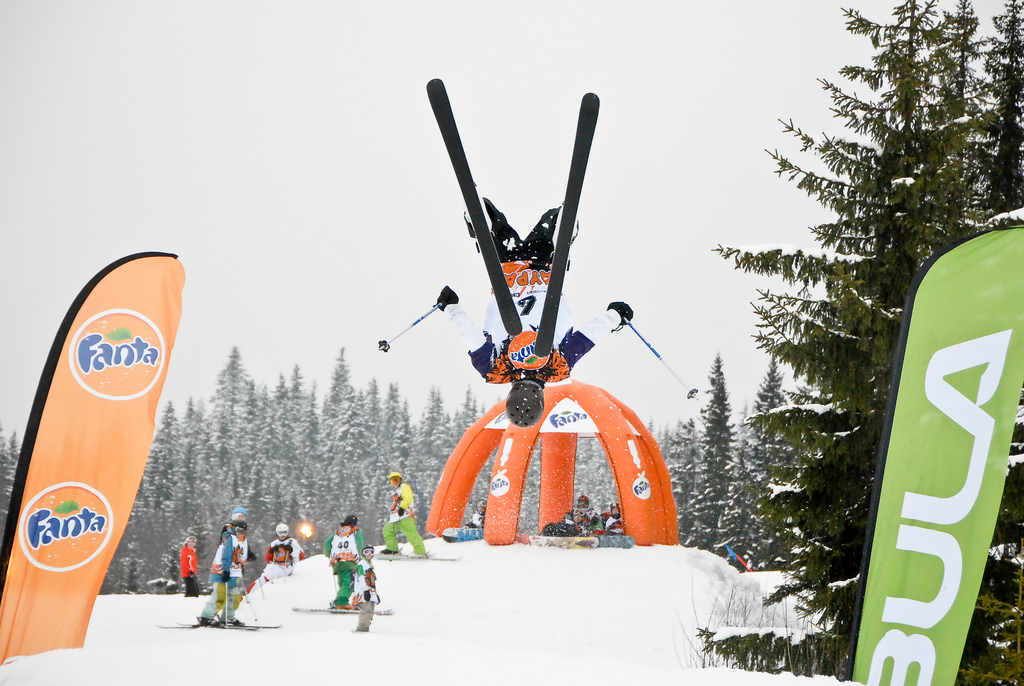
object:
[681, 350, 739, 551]
tree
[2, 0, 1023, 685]
woods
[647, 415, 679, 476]
tree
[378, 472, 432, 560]
person